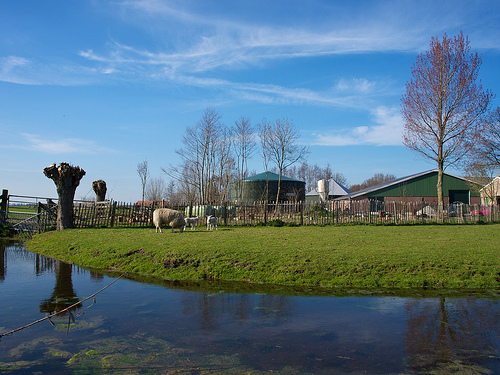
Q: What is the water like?
A: Murky.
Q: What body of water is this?
A: Pond.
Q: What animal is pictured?
A: Cow.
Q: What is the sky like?
A: Clear.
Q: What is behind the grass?
A: Fence.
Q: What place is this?
A: Farm.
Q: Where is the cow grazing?
A: Field.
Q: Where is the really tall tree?
A: In front of house.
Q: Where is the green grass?
A: Next to the water.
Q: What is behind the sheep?
A: Wooden fence.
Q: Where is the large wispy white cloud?
A: In the blue sky.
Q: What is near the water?
A: Lamb.